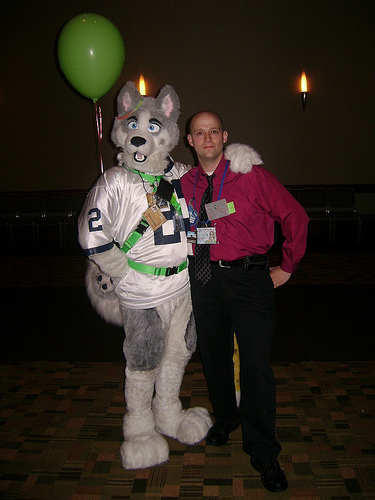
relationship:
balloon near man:
[54, 10, 129, 110] [180, 111, 309, 492]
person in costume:
[77, 82, 215, 476] [112, 85, 202, 473]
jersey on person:
[71, 169, 191, 308] [77, 82, 215, 476]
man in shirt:
[175, 112, 322, 493] [183, 163, 308, 274]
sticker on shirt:
[189, 195, 254, 246] [183, 163, 308, 274]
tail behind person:
[76, 258, 134, 336] [77, 82, 215, 476]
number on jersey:
[84, 193, 183, 257] [71, 169, 191, 308]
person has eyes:
[77, 82, 215, 476] [123, 119, 168, 129]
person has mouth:
[77, 82, 215, 476] [128, 148, 149, 165]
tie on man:
[193, 176, 220, 288] [175, 112, 322, 493]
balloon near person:
[54, 10, 129, 110] [77, 82, 215, 476]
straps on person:
[110, 162, 199, 293] [77, 82, 215, 476]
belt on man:
[184, 255, 274, 271] [175, 112, 322, 493]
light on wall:
[286, 67, 322, 121] [1, 1, 374, 243]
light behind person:
[286, 67, 322, 121] [77, 82, 215, 476]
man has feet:
[175, 112, 322, 493] [197, 419, 297, 494]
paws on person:
[119, 403, 221, 474] [77, 82, 215, 476]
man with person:
[175, 112, 322, 493] [77, 82, 215, 476]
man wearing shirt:
[175, 112, 322, 493] [183, 163, 308, 274]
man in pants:
[175, 112, 322, 493] [185, 258, 286, 459]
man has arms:
[175, 112, 322, 493] [182, 171, 323, 285]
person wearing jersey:
[77, 82, 215, 476] [71, 169, 191, 308]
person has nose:
[77, 82, 215, 476] [126, 136, 146, 149]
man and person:
[175, 112, 322, 493] [77, 82, 215, 476]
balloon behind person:
[54, 10, 129, 110] [77, 82, 215, 476]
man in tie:
[175, 112, 322, 493] [193, 176, 220, 288]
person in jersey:
[77, 82, 215, 476] [71, 169, 191, 308]